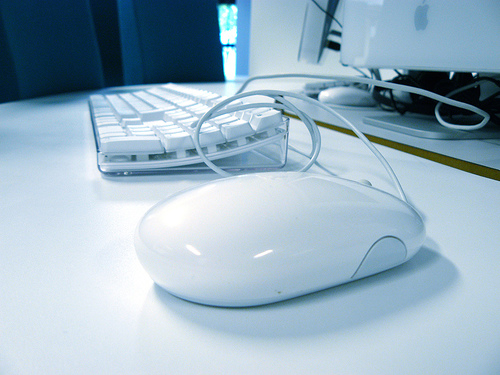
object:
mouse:
[134, 170, 426, 307]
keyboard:
[89, 83, 290, 173]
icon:
[414, 0, 429, 31]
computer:
[339, 0, 500, 140]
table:
[0, 83, 499, 375]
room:
[0, 0, 499, 375]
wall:
[236, 0, 344, 81]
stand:
[363, 115, 500, 141]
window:
[217, 1, 240, 83]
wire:
[193, 73, 491, 202]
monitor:
[340, 0, 499, 74]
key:
[100, 136, 163, 153]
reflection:
[186, 245, 201, 256]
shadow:
[154, 236, 459, 338]